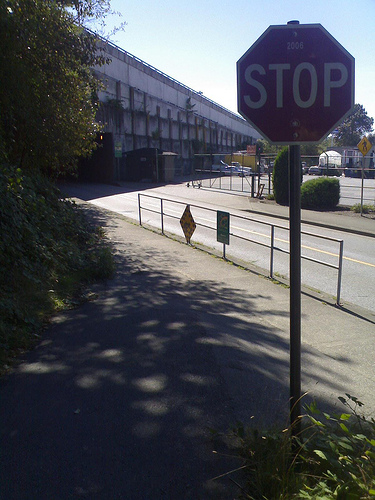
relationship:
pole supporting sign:
[283, 139, 310, 466] [233, 22, 357, 161]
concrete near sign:
[5, 192, 373, 499] [233, 22, 357, 161]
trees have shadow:
[2, 1, 129, 403] [5, 204, 350, 499]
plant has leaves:
[200, 380, 371, 499] [338, 411, 354, 423]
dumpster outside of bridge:
[122, 143, 180, 190] [73, 19, 271, 185]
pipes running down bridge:
[128, 86, 139, 159] [73, 19, 271, 185]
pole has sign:
[283, 139, 310, 466] [233, 22, 357, 161]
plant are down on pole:
[200, 380, 371, 499] [283, 139, 310, 466]